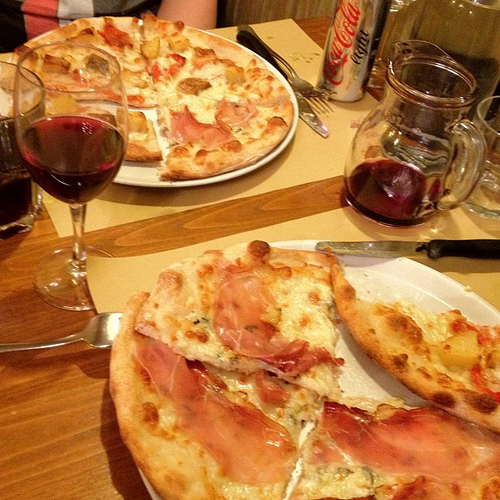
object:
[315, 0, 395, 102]
coca-cola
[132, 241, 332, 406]
pie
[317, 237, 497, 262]
knife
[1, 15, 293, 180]
pizza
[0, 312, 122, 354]
fork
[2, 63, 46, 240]
glass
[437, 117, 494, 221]
handle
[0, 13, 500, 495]
table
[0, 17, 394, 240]
papermat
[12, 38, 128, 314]
glass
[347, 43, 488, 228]
glass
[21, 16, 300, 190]
plate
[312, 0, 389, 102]
can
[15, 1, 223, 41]
person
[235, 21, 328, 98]
fork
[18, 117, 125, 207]
red wine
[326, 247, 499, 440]
pizza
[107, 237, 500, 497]
plate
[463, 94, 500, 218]
glass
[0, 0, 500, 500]
pitcher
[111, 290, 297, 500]
ham